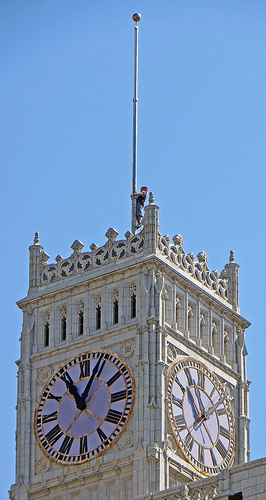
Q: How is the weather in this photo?
A: It is clear.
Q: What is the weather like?
A: It is clear.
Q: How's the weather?
A: It is clear.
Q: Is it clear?
A: Yes, it is clear.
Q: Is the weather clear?
A: Yes, it is clear.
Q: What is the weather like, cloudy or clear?
A: It is clear.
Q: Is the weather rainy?
A: No, it is clear.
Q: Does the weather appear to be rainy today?
A: No, it is clear.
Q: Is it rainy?
A: No, it is clear.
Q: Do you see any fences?
A: No, there are no fences.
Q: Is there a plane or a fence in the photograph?
A: No, there are no fences or airplanes.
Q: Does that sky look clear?
A: Yes, the sky is clear.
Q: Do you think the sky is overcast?
A: No, the sky is clear.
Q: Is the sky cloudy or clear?
A: The sky is clear.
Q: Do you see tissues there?
A: No, there are no tissues.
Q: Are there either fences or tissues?
A: No, there are no tissues or fences.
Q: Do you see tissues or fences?
A: No, there are no tissues or fences.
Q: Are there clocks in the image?
A: Yes, there is a clock.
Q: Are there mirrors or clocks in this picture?
A: Yes, there is a clock.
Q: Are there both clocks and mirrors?
A: No, there is a clock but no mirrors.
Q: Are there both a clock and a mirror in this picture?
A: No, there is a clock but no mirrors.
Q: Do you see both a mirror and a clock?
A: No, there is a clock but no mirrors.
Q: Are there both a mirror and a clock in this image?
A: No, there is a clock but no mirrors.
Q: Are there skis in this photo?
A: No, there are no skis.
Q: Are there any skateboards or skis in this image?
A: No, there are no skis or skateboards.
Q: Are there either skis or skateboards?
A: No, there are no skis or skateboards.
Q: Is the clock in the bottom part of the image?
A: Yes, the clock is in the bottom of the image.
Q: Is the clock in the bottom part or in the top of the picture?
A: The clock is in the bottom of the image.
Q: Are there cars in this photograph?
A: No, there are no cars.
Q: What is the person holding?
A: The person is holding the pole.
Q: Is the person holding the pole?
A: Yes, the person is holding the pole.